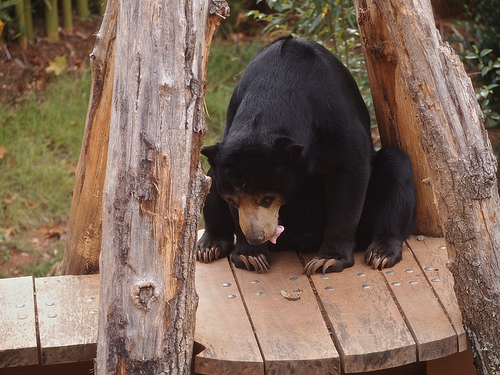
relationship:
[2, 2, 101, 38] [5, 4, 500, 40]
bamboo on background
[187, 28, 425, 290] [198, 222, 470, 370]
bear sitting on wood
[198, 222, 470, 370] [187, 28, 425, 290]
planks under bear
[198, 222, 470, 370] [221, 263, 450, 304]
wood has metal bolts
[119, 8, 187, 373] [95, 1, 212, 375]
bark on log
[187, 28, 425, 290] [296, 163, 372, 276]
bear has back leg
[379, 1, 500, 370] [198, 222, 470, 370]
trunk curving over platform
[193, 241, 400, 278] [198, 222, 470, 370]
nails in platform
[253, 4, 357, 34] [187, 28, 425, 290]
bush behind bear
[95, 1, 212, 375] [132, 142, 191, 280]
log has marks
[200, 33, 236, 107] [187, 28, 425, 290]
grass behind bear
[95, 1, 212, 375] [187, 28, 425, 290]
log next to bear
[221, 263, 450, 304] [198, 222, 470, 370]
studs on wood slat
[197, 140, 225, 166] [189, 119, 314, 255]
ear on head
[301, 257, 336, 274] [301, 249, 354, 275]
nails on paw